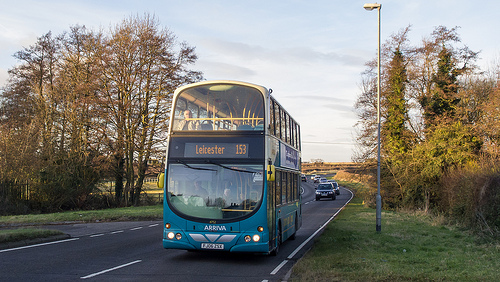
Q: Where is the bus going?
A: Leicester.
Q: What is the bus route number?
A: 153.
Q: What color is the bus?
A: Blue.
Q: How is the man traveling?
A: By bus.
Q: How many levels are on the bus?
A: Two.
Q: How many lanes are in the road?
A: Two.